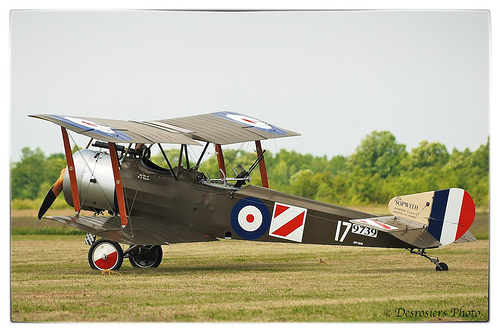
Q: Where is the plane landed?
A: On the ground.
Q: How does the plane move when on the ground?
A: On it's wheels.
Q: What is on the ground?
A: A plane.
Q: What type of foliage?
A: Tree.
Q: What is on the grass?
A: A plane.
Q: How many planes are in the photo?
A: One.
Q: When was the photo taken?
A: Daytime.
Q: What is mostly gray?
A: Airplane.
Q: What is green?
A: Grass.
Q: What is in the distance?
A: Trees.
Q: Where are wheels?
A: Underneath the plane.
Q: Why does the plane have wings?
A: To fly.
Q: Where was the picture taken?
A: At a airshow.